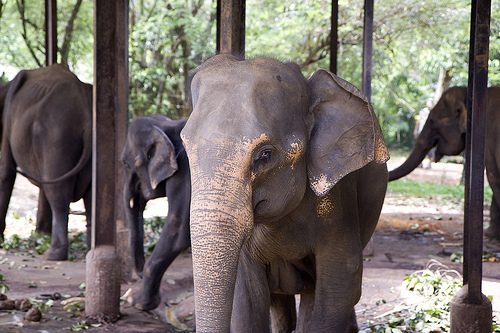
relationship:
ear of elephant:
[294, 71, 394, 180] [157, 31, 387, 326]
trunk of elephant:
[183, 140, 250, 328] [157, 31, 387, 326]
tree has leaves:
[393, 12, 494, 187] [333, 12, 498, 49]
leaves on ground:
[405, 241, 470, 324] [406, 193, 455, 330]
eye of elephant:
[246, 144, 283, 173] [157, 31, 387, 326]